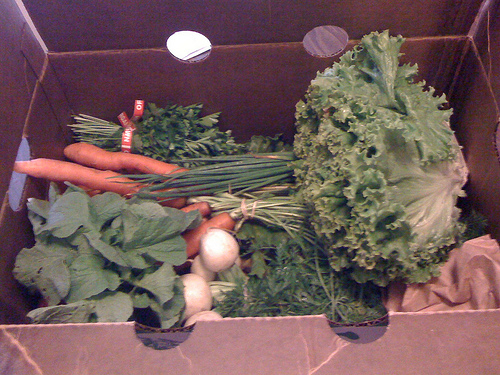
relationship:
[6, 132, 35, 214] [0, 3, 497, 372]
handhold for carrying box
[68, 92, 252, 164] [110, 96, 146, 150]
produce tied with band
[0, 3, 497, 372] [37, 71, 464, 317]
box with vegetables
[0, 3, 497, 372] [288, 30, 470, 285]
box with vegetables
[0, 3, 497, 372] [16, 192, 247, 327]
box with vegetables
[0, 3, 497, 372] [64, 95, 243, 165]
box with vegetables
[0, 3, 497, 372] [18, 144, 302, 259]
box with vegetables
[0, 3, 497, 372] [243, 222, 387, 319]
box with vegetables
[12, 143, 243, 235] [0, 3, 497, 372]
carrots in box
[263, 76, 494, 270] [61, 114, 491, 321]
cabbage with vegetables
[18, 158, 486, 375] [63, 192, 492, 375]
box filled vegetables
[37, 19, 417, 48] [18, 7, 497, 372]
surface of table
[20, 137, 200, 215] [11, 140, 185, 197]
skin of carrots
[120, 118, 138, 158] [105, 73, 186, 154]
lettering on label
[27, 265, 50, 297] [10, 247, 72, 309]
caterpillar holes in leaf